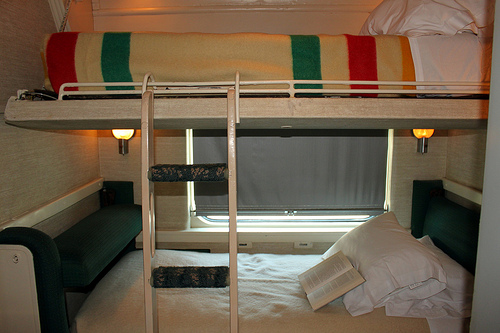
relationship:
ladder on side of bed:
[139, 71, 242, 333] [39, 19, 474, 134]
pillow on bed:
[320, 211, 448, 318] [96, 237, 465, 329]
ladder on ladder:
[139, 71, 242, 333] [136, 77, 252, 311]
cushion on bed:
[52, 203, 142, 287] [41, 211, 497, 320]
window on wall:
[186, 127, 393, 228] [107, 77, 472, 247]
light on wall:
[410, 128, 435, 155] [379, 100, 475, 247]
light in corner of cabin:
[396, 120, 450, 152] [392, 110, 461, 253]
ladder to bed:
[136, 77, 252, 311] [3, 71, 494, 129]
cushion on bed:
[52, 203, 142, 287] [58, 215, 468, 331]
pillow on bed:
[320, 211, 448, 318] [332, 213, 453, 327]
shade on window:
[217, 131, 386, 211] [154, 99, 441, 262]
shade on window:
[217, 131, 386, 211] [156, 102, 406, 236]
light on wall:
[98, 122, 141, 165] [79, 131, 193, 234]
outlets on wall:
[228, 239, 322, 268] [208, 213, 422, 256]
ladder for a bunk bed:
[136, 77, 252, 311] [110, 248, 473, 331]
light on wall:
[110, 129, 134, 156] [90, 111, 204, 260]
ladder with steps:
[139, 71, 242, 333] [154, 162, 223, 296]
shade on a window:
[217, 131, 386, 211] [138, 84, 412, 247]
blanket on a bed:
[160, 101, 385, 144] [159, 50, 312, 67]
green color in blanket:
[306, 99, 362, 133] [192, 51, 397, 73]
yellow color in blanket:
[206, 57, 261, 73] [217, 103, 291, 133]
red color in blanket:
[353, 100, 387, 133] [53, 66, 460, 79]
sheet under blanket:
[41, 29, 493, 98] [306, 100, 333, 133]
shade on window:
[265, 159, 314, 238] [254, 127, 364, 192]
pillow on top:
[320, 211, 448, 318] [372, 256, 421, 317]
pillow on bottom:
[384, 235, 474, 319] [435, 270, 460, 333]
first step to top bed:
[154, 264, 222, 333] [3, 71, 494, 129]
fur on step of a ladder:
[150, 274, 240, 325] [122, 175, 254, 333]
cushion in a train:
[52, 203, 142, 287] [36, 189, 125, 333]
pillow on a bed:
[358, 258, 435, 293] [142, 212, 483, 333]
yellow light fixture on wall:
[98, 121, 158, 201] [102, 101, 143, 193]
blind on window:
[244, 194, 347, 234] [194, 135, 414, 258]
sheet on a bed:
[404, 52, 478, 83] [194, 102, 225, 118]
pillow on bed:
[320, 211, 448, 318] [34, 154, 462, 322]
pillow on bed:
[384, 235, 474, 319] [34, 154, 462, 322]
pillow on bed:
[320, 211, 448, 318] [63, 192, 462, 330]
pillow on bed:
[355, 225, 464, 310] [63, 192, 462, 330]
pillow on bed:
[320, 211, 448, 318] [68, 210, 433, 327]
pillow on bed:
[320, 211, 448, 318] [74, 221, 467, 327]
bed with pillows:
[113, 207, 446, 329] [315, 190, 456, 326]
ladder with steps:
[139, 71, 242, 333] [139, 155, 244, 302]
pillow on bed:
[363, 0, 480, 49] [1, 16, 479, 90]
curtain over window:
[178, 114, 395, 220] [177, 112, 389, 226]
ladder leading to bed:
[139, 71, 242, 333] [3, 71, 494, 129]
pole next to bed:
[220, 60, 247, 324] [64, 240, 477, 315]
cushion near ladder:
[22, 171, 144, 286] [139, 71, 242, 333]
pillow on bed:
[320, 211, 448, 318] [84, 226, 468, 324]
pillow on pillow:
[320, 211, 448, 318] [332, 221, 442, 324]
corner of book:
[333, 262, 386, 296] [294, 250, 375, 308]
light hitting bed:
[226, 238, 332, 295] [84, 226, 468, 324]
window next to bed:
[177, 112, 389, 226] [16, 234, 479, 326]